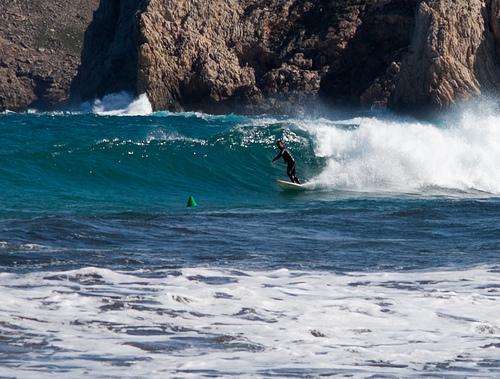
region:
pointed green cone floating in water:
[153, 180, 210, 217]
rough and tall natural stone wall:
[25, 15, 480, 100]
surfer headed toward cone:
[160, 126, 340, 217]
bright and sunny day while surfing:
[137, 95, 354, 242]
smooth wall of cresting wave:
[52, 125, 257, 190]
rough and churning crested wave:
[300, 112, 482, 202]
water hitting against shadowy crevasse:
[45, 16, 172, 122]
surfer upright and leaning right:
[231, 135, 331, 201]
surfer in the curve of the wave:
[222, 101, 337, 193]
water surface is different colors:
[58, 123, 354, 333]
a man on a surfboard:
[270, 138, 316, 189]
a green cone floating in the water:
[185, 195, 195, 205]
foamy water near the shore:
[2, 270, 494, 370]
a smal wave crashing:
[296, 115, 496, 200]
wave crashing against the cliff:
[60, 85, 155, 115]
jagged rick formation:
[146, 0, 351, 110]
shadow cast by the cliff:
[70, 0, 145, 105]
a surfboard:
[272, 175, 307, 185]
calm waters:
[10, 215, 492, 255]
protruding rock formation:
[380, 0, 493, 110]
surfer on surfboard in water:
[266, 138, 320, 194]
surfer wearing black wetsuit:
[271, 135, 301, 183]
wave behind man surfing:
[59, 117, 490, 206]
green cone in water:
[182, 191, 200, 209]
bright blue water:
[8, 106, 498, 374]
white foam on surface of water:
[3, 264, 498, 377]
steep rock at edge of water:
[0, 1, 497, 118]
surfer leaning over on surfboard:
[265, 136, 303, 188]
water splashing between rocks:
[74, 77, 154, 117]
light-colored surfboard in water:
[276, 175, 311, 193]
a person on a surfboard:
[254, 133, 325, 199]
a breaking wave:
[297, 97, 489, 194]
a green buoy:
[173, 179, 209, 222]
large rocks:
[128, 10, 340, 101]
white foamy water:
[41, 267, 471, 362]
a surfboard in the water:
[268, 173, 325, 190]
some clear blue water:
[42, 205, 185, 245]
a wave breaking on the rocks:
[63, 83, 183, 118]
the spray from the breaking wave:
[410, 80, 495, 130]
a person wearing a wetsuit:
[263, 140, 304, 178]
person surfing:
[261, 130, 321, 195]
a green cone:
[184, 187, 199, 219]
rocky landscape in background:
[8, 0, 494, 124]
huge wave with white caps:
[316, 96, 495, 192]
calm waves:
[17, 269, 498, 373]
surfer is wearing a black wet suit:
[258, 128, 321, 192]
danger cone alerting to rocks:
[177, 182, 215, 232]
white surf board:
[274, 172, 318, 195]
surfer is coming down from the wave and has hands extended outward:
[266, 133, 315, 205]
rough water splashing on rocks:
[86, 87, 154, 164]